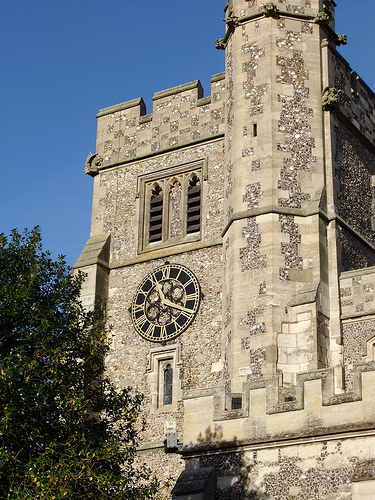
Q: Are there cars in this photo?
A: No, there are no cars.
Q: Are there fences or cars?
A: No, there are no cars or fences.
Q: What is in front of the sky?
A: The tree is in front of the sky.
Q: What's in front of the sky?
A: The tree is in front of the sky.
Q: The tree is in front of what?
A: The tree is in front of the sky.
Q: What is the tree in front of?
A: The tree is in front of the sky.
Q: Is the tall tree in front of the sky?
A: Yes, the tree is in front of the sky.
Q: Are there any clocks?
A: Yes, there is a clock.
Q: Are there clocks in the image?
A: Yes, there is a clock.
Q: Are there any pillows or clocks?
A: Yes, there is a clock.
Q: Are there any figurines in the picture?
A: No, there are no figurines.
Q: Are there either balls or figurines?
A: No, there are no figurines or balls.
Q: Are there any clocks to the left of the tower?
A: Yes, there is a clock to the left of the tower.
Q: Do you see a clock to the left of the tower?
A: Yes, there is a clock to the left of the tower.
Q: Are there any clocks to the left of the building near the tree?
A: Yes, there is a clock to the left of the tower.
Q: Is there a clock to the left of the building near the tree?
A: Yes, there is a clock to the left of the tower.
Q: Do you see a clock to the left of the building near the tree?
A: Yes, there is a clock to the left of the tower.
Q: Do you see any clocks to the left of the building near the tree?
A: Yes, there is a clock to the left of the tower.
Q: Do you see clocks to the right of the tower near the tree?
A: No, the clock is to the left of the tower.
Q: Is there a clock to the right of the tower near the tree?
A: No, the clock is to the left of the tower.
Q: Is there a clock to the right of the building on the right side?
A: No, the clock is to the left of the tower.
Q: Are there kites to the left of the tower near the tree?
A: No, there is a clock to the left of the tower.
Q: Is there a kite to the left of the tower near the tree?
A: No, there is a clock to the left of the tower.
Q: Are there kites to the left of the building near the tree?
A: No, there is a clock to the left of the tower.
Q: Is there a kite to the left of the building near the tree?
A: No, there is a clock to the left of the tower.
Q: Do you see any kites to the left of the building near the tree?
A: No, there is a clock to the left of the tower.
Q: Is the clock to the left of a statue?
A: No, the clock is to the left of the tower.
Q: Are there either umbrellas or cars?
A: No, there are no cars or umbrellas.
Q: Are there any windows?
A: Yes, there is a window.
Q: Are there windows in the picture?
A: Yes, there is a window.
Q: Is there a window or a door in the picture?
A: Yes, there is a window.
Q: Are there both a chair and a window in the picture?
A: No, there is a window but no chairs.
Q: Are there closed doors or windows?
A: Yes, there is a closed window.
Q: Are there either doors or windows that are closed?
A: Yes, the window is closed.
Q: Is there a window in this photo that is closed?
A: Yes, there is a closed window.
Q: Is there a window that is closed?
A: Yes, there is a window that is closed.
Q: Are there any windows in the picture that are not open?
A: Yes, there is an closed window.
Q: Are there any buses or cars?
A: No, there are no cars or buses.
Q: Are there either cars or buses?
A: No, there are no cars or buses.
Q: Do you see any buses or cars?
A: No, there are no cars or buses.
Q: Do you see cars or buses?
A: No, there are no cars or buses.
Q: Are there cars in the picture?
A: No, there are no cars.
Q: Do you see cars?
A: No, there are no cars.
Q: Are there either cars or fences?
A: No, there are no cars or fences.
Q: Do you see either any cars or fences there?
A: No, there are no cars or fences.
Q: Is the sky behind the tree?
A: Yes, the sky is behind the tree.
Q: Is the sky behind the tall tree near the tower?
A: Yes, the sky is behind the tree.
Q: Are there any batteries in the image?
A: No, there are no batteries.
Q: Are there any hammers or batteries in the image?
A: No, there are no batteries or hammers.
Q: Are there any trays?
A: No, there are no trays.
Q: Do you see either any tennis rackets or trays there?
A: No, there are no trays or tennis rackets.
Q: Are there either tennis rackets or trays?
A: No, there are no trays or tennis rackets.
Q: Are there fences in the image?
A: No, there are no fences.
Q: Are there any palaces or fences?
A: No, there are no fences or palaces.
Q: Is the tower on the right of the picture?
A: Yes, the tower is on the right of the image.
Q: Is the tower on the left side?
A: No, the tower is on the right of the image.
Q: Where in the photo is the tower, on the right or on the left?
A: The tower is on the right of the image.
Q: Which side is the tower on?
A: The tower is on the right of the image.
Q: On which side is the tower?
A: The tower is on the right of the image.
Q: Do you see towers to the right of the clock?
A: Yes, there is a tower to the right of the clock.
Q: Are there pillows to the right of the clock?
A: No, there is a tower to the right of the clock.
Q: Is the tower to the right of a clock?
A: Yes, the tower is to the right of a clock.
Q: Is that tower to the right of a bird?
A: No, the tower is to the right of a clock.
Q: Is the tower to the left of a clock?
A: No, the tower is to the right of a clock.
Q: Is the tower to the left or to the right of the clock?
A: The tower is to the right of the clock.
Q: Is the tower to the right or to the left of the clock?
A: The tower is to the right of the clock.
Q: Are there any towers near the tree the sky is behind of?
A: Yes, there is a tower near the tree.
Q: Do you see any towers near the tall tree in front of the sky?
A: Yes, there is a tower near the tree.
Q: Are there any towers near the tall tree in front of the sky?
A: Yes, there is a tower near the tree.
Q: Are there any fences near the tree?
A: No, there is a tower near the tree.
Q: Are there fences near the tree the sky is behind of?
A: No, there is a tower near the tree.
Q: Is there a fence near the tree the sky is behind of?
A: No, there is a tower near the tree.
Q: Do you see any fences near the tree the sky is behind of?
A: No, there is a tower near the tree.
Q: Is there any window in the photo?
A: Yes, there is a window.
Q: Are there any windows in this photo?
A: Yes, there is a window.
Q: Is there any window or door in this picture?
A: Yes, there is a window.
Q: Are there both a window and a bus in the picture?
A: No, there is a window but no buses.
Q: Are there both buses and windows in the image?
A: No, there is a window but no buses.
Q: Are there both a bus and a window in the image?
A: No, there is a window but no buses.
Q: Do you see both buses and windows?
A: No, there is a window but no buses.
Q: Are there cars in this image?
A: No, there are no cars.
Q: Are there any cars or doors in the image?
A: No, there are no cars or doors.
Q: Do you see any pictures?
A: No, there are no pictures.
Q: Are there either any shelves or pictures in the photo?
A: No, there are no pictures or shelves.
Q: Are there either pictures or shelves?
A: No, there are no pictures or shelves.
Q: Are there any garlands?
A: No, there are no garlands.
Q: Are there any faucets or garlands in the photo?
A: No, there are no garlands or faucets.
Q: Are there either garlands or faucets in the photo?
A: No, there are no garlands or faucets.